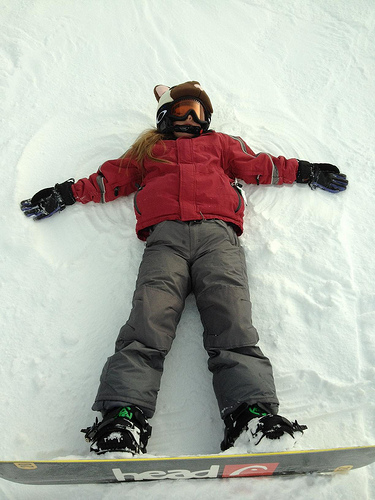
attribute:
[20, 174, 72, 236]
hand — girl's